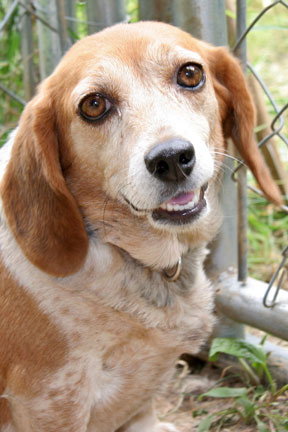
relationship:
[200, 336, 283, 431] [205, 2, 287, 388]
plant beside fence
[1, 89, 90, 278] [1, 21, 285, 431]
ear on dog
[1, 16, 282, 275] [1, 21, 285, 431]
head of dog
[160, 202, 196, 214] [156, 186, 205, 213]
teeth in mouth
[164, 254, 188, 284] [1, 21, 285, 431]
ring on dog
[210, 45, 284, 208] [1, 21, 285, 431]
ear of dog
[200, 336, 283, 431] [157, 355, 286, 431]
plant on ground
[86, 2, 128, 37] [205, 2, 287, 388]
post on fence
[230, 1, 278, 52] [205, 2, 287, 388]
link of fence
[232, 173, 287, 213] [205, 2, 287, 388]
link on fence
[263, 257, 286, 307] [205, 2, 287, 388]
link on fence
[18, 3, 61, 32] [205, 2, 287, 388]
link on fence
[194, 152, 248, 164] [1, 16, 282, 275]
whisker on head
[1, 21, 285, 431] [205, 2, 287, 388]
dog in front of fence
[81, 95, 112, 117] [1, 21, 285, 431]
eye on dog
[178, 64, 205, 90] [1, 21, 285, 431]
eye on dog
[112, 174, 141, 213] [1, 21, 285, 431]
whisker on dog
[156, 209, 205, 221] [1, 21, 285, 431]
lip of dog